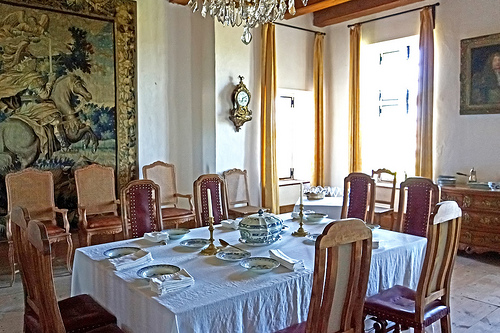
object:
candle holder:
[198, 216, 221, 257]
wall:
[215, 45, 260, 167]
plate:
[240, 256, 280, 274]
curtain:
[271, 26, 316, 92]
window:
[271, 87, 315, 180]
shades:
[341, 8, 443, 195]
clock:
[228, 75, 253, 133]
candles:
[206, 188, 215, 218]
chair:
[363, 199, 464, 332]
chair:
[390, 177, 440, 236]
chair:
[339, 171, 375, 222]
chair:
[10, 218, 126, 332]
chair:
[299, 215, 376, 332]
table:
[67, 212, 431, 333]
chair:
[3, 166, 73, 287]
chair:
[72, 162, 129, 246]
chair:
[140, 157, 194, 228]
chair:
[221, 167, 266, 217]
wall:
[442, 120, 498, 174]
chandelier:
[184, 0, 313, 45]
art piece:
[2, 0, 141, 229]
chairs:
[119, 179, 167, 241]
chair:
[301, 216, 371, 332]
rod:
[346, 3, 443, 31]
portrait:
[457, 31, 500, 116]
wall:
[439, 3, 497, 32]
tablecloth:
[69, 209, 434, 332]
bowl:
[136, 262, 183, 282]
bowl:
[240, 256, 280, 275]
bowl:
[160, 227, 191, 238]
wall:
[0, 3, 213, 272]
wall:
[213, 10, 333, 210]